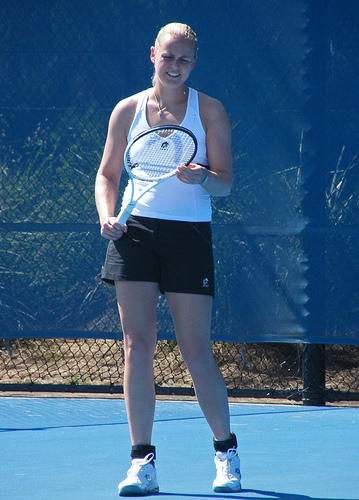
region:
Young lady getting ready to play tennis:
[92, 20, 240, 493]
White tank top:
[118, 85, 210, 220]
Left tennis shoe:
[207, 447, 237, 492]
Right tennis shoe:
[115, 455, 157, 492]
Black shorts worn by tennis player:
[93, 212, 214, 296]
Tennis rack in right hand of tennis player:
[106, 120, 196, 247]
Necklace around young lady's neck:
[148, 77, 181, 120]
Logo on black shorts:
[193, 268, 213, 288]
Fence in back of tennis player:
[0, 339, 355, 395]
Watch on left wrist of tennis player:
[196, 162, 213, 191]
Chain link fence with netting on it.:
[1, 6, 87, 381]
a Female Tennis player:
[84, 20, 241, 496]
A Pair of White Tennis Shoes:
[104, 437, 262, 497]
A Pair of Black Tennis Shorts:
[97, 206, 228, 304]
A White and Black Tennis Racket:
[116, 114, 193, 242]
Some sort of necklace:
[146, 85, 195, 117]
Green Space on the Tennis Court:
[252, 408, 357, 496]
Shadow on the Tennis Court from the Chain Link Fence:
[4, 391, 126, 427]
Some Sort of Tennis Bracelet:
[197, 167, 209, 193]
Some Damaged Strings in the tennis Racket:
[129, 154, 185, 171]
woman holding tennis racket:
[87, 18, 247, 412]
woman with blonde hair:
[148, 21, 196, 83]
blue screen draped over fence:
[243, 31, 332, 339]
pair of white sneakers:
[113, 434, 244, 492]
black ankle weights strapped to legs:
[120, 427, 240, 457]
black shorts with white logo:
[94, 207, 217, 302]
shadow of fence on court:
[19, 400, 115, 431]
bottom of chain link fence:
[9, 337, 120, 378]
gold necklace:
[142, 79, 192, 124]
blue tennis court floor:
[26, 403, 353, 495]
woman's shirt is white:
[110, 94, 220, 231]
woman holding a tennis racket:
[97, 102, 200, 243]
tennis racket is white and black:
[104, 112, 207, 228]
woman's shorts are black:
[99, 203, 241, 288]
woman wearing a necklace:
[144, 76, 194, 145]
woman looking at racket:
[132, 22, 214, 97]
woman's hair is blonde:
[134, 6, 210, 95]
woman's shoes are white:
[98, 445, 261, 491]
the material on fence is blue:
[0, 4, 356, 345]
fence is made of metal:
[0, 331, 352, 424]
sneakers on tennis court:
[113, 449, 248, 496]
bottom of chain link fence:
[252, 341, 302, 402]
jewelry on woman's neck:
[146, 96, 183, 121]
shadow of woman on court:
[248, 481, 295, 496]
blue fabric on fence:
[245, 194, 316, 348]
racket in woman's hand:
[99, 126, 197, 240]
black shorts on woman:
[92, 213, 227, 300]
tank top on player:
[115, 89, 216, 223]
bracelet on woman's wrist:
[196, 164, 212, 189]